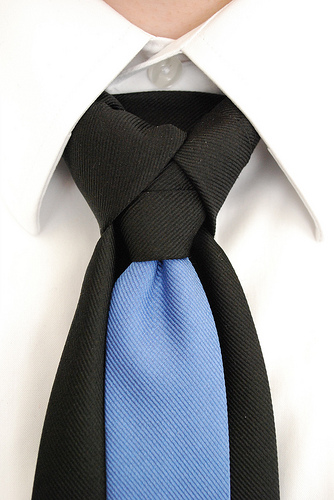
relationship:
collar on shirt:
[179, 1, 321, 232] [5, 1, 322, 495]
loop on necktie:
[79, 91, 243, 241] [40, 84, 307, 498]